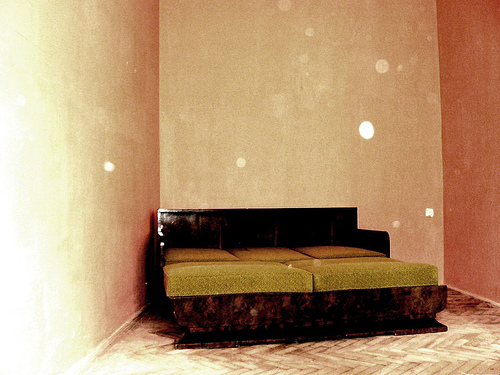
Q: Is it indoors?
A: Yes, it is indoors.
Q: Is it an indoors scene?
A: Yes, it is indoors.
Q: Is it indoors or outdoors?
A: It is indoors.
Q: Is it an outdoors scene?
A: No, it is indoors.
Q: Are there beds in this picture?
A: Yes, there is a bed.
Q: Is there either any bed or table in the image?
A: Yes, there is a bed.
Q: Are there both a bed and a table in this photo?
A: No, there is a bed but no tables.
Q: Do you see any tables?
A: No, there are no tables.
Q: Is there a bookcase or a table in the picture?
A: No, there are no tables or bookcases.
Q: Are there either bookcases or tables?
A: No, there are no tables or bookcases.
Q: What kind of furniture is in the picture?
A: The furniture is a bed.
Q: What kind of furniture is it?
A: The piece of furniture is a bed.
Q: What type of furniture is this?
A: That is a bed.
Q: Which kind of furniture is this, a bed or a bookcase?
A: That is a bed.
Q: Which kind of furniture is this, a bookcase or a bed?
A: That is a bed.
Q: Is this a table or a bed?
A: This is a bed.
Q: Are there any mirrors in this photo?
A: No, there are no mirrors.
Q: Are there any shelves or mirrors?
A: No, there are no mirrors or shelves.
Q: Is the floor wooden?
A: Yes, the floor is wooden.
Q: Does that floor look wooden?
A: Yes, the floor is wooden.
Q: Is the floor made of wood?
A: Yes, the floor is made of wood.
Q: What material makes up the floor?
A: The floor is made of wood.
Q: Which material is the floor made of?
A: The floor is made of wood.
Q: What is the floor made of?
A: The floor is made of wood.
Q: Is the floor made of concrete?
A: No, the floor is made of wood.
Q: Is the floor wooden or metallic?
A: The floor is wooden.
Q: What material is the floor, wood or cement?
A: The floor is made of wood.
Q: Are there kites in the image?
A: No, there are no kites.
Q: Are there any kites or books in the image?
A: No, there are no kites or books.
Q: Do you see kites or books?
A: No, there are no kites or books.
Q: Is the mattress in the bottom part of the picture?
A: Yes, the mattress is in the bottom of the image.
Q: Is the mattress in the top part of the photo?
A: No, the mattress is in the bottom of the image.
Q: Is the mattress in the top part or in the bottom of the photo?
A: The mattress is in the bottom of the image.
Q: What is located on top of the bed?
A: The mattress is on top of the bed.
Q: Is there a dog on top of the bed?
A: No, there is a mattress on top of the bed.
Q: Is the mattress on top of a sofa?
A: No, the mattress is on top of the bed.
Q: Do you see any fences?
A: No, there are no fences.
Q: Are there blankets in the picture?
A: No, there are no blankets.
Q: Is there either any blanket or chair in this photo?
A: No, there are no blankets or chairs.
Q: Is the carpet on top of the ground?
A: Yes, the carpet is on top of the ground.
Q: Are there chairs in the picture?
A: No, there are no chairs.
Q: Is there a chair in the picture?
A: No, there are no chairs.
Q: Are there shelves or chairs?
A: No, there are no chairs or shelves.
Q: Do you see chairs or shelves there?
A: No, there are no chairs or shelves.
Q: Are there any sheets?
A: No, there are no sheets.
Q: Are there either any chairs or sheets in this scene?
A: No, there are no sheets or chairs.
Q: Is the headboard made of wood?
A: Yes, the headboard is made of wood.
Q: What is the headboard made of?
A: The headboard is made of wood.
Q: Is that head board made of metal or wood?
A: The head board is made of wood.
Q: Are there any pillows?
A: Yes, there are pillows.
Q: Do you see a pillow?
A: Yes, there are pillows.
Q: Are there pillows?
A: Yes, there are pillows.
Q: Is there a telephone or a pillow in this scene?
A: Yes, there are pillows.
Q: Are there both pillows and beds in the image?
A: Yes, there are both pillows and a bed.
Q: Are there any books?
A: No, there are no books.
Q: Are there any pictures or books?
A: No, there are no books or pictures.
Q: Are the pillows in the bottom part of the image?
A: Yes, the pillows are in the bottom of the image.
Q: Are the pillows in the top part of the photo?
A: No, the pillows are in the bottom of the image.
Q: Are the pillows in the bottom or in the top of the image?
A: The pillows are in the bottom of the image.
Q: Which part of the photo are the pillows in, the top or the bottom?
A: The pillows are in the bottom of the image.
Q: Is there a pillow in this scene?
A: Yes, there is a pillow.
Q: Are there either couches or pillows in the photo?
A: Yes, there is a pillow.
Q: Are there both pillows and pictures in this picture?
A: No, there is a pillow but no pictures.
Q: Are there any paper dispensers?
A: No, there are no paper dispensers.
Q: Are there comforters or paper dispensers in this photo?
A: No, there are no paper dispensers or comforters.